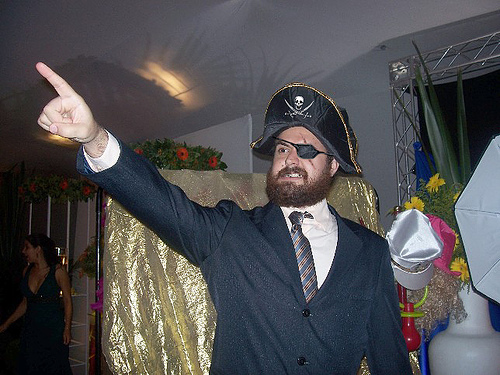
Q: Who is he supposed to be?
A: Pirate.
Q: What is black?
A: His hat.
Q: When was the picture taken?
A: Nighttime.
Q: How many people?
A: One.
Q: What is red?
A: The flowers to the left.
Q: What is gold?
A: The cover behind him.